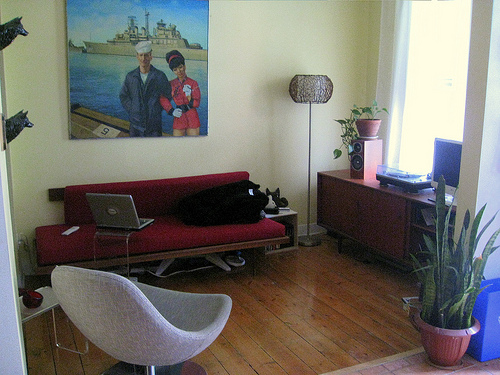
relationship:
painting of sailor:
[46, 6, 221, 148] [117, 39, 173, 146]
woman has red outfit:
[154, 45, 207, 137] [154, 73, 208, 127]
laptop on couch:
[83, 181, 154, 235] [28, 167, 296, 284]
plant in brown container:
[400, 180, 498, 336] [406, 314, 488, 369]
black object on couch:
[160, 174, 291, 232] [28, 167, 296, 284]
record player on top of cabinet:
[372, 160, 436, 199] [310, 164, 457, 278]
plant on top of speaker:
[328, 97, 395, 157] [345, 130, 385, 183]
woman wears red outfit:
[154, 45, 207, 137] [154, 73, 208, 127]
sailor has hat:
[117, 39, 173, 146] [130, 34, 156, 59]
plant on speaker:
[328, 97, 395, 157] [345, 130, 385, 183]